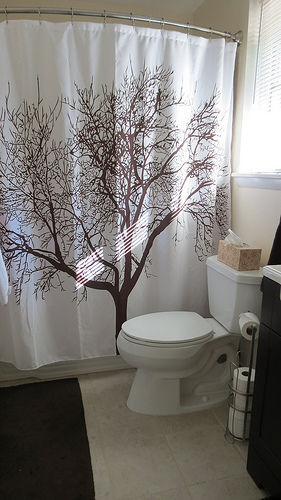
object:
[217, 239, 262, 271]
kleenex box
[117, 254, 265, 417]
toilet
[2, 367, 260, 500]
floor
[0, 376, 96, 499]
rug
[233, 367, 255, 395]
toilet paper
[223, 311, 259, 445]
holder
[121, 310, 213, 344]
lid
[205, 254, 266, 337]
tank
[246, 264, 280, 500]
cupboard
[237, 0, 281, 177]
window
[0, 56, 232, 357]
tree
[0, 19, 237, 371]
shower curtain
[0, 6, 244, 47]
rod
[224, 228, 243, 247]
tissues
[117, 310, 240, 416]
base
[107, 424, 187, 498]
tile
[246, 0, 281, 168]
blinds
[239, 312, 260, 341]
toilet paper